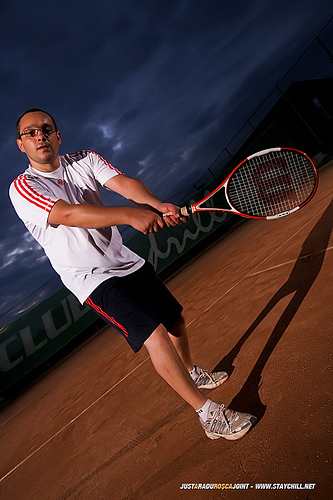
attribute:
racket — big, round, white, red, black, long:
[170, 141, 316, 235]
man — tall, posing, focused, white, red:
[7, 94, 315, 443]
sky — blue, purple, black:
[4, 5, 307, 281]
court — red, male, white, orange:
[1, 163, 333, 498]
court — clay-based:
[34, 284, 331, 498]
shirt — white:
[1, 147, 149, 312]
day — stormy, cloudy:
[5, 8, 330, 495]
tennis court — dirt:
[67, 217, 332, 496]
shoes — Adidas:
[187, 356, 260, 443]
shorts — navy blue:
[84, 260, 189, 356]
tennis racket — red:
[158, 139, 328, 226]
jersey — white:
[3, 143, 148, 310]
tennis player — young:
[3, 98, 263, 450]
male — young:
[3, 98, 262, 449]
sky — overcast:
[44, 13, 301, 102]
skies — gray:
[56, 17, 194, 106]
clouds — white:
[93, 109, 192, 182]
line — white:
[44, 364, 127, 441]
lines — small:
[194, 402, 206, 417]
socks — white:
[184, 367, 215, 423]